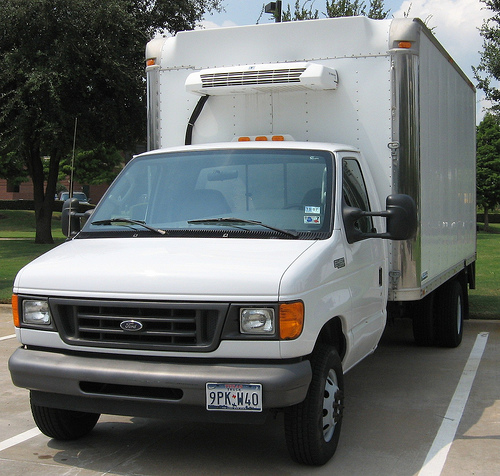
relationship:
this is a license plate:
[205, 380, 261, 413] [201, 385, 269, 413]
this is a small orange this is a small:
[238, 130, 252, 146] [238, 135, 252, 141]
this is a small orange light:
[258, 134, 268, 142] [255, 137, 269, 142]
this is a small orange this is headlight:
[275, 134, 284, 141] [272, 135, 284, 142]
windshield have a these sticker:
[128, 154, 317, 214] [303, 205, 319, 212]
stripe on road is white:
[440, 335, 466, 450] [451, 378, 463, 429]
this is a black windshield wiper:
[191, 217, 260, 229] [191, 210, 276, 236]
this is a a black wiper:
[90, 218, 150, 230] [95, 217, 150, 230]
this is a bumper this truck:
[10, 354, 281, 412] [8, 16, 477, 466]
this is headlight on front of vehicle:
[230, 134, 291, 144] [142, 128, 366, 219]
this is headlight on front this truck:
[390, 36, 413, 50] [8, 16, 477, 466]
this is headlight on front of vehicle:
[141, 60, 165, 67] [142, 128, 366, 219]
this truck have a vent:
[184, 70, 452, 323] [176, 64, 335, 91]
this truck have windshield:
[8, 16, 477, 466] [110, 170, 327, 236]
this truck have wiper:
[8, 16, 477, 466] [191, 210, 276, 236]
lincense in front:
[204, 385, 267, 413] [79, 365, 311, 412]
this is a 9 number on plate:
[210, 390, 216, 406] [206, 381, 263, 413]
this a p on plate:
[216, 391, 226, 411] [206, 381, 263, 413]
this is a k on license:
[225, 391, 232, 405] [204, 385, 267, 413]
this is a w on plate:
[239, 388, 247, 409] [206, 381, 263, 413]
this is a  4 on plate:
[246, 395, 254, 411] [206, 381, 263, 413]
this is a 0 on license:
[252, 390, 259, 404] [204, 385, 267, 413]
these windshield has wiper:
[110, 170, 327, 236] [191, 210, 276, 236]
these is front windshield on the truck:
[110, 170, 327, 236] [131, 60, 363, 322]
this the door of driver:
[335, 168, 382, 319] [343, 176, 375, 221]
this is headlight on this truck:
[230, 134, 291, 144] [8, 16, 477, 466]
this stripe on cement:
[6, 435, 33, 445] [6, 414, 42, 449]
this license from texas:
[204, 385, 267, 413] [231, 394, 237, 403]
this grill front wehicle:
[55, 302, 219, 350] [94, 155, 348, 389]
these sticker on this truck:
[303, 205, 319, 218] [8, 16, 477, 466]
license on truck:
[204, 385, 267, 413] [144, 45, 472, 363]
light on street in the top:
[262, 1, 291, 14] [259, 1, 296, 18]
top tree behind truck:
[62, 9, 304, 98] [144, 45, 472, 363]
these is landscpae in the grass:
[10, 206, 76, 251] [5, 233, 29, 262]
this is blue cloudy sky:
[252, 6, 388, 23] [203, 3, 394, 19]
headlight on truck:
[236, 131, 286, 141] [144, 45, 472, 363]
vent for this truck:
[176, 64, 335, 91] [8, 16, 477, 466]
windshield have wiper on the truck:
[128, 154, 317, 214] [131, 60, 363, 322]